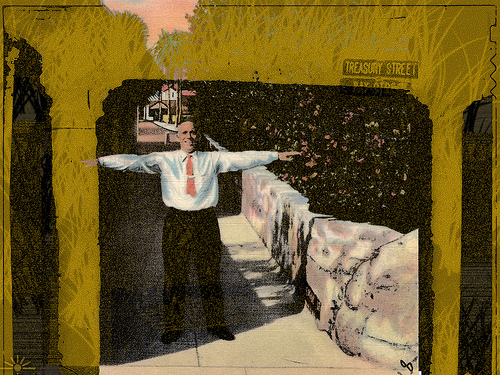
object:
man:
[80, 121, 302, 345]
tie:
[185, 154, 199, 197]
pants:
[162, 207, 226, 329]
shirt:
[98, 149, 280, 210]